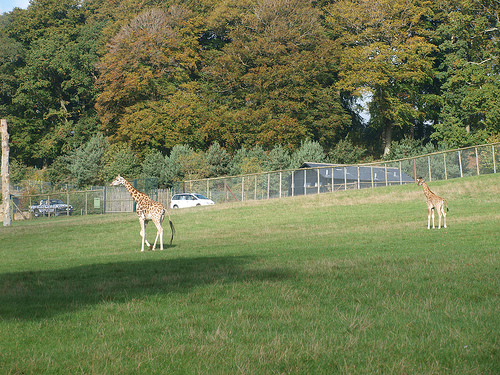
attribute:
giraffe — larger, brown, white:
[112, 175, 175, 252]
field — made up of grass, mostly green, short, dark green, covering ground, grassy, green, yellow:
[1, 171, 499, 374]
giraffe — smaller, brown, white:
[415, 178, 452, 231]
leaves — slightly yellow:
[96, 3, 433, 145]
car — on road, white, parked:
[171, 194, 212, 211]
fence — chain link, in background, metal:
[9, 141, 498, 225]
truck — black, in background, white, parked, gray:
[31, 200, 73, 218]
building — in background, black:
[286, 163, 420, 201]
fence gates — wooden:
[104, 182, 173, 215]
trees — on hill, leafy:
[3, 3, 499, 200]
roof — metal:
[309, 159, 416, 184]